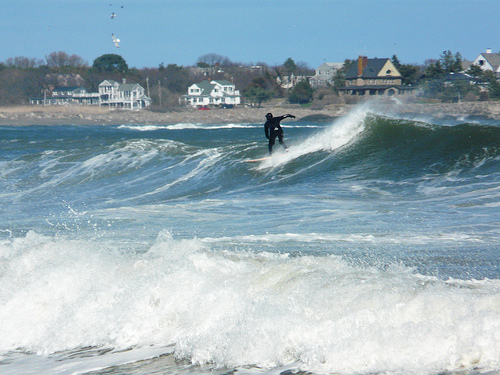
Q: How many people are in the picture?
A: One.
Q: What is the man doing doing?
A: Surfing.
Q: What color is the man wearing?
A: Black.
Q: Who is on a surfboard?
A: A man.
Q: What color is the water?
A: Blue.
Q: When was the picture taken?
A: During the day.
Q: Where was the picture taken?
A: In the ocean.